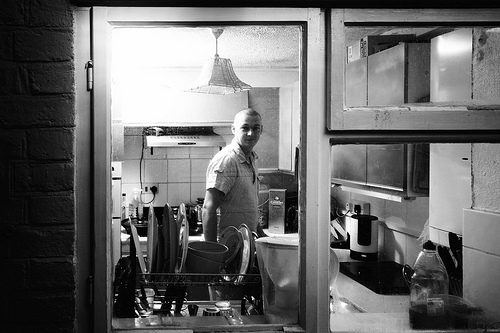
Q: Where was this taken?
A: Kitchen.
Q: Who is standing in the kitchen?
A: Man.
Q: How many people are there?
A: 1.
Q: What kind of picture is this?
A: Black and white.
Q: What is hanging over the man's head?
A: Light.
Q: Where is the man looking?
A: At the camera.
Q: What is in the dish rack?
A: Dishes.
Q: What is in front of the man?
A: Cabinets.